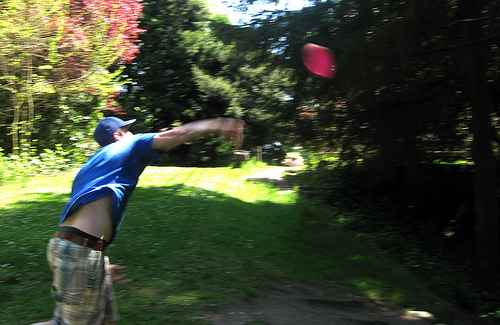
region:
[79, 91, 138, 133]
the cap is blue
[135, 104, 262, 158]
the arm is extended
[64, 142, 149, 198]
the shirt is blue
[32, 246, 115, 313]
the shorts are plaid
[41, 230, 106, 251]
the belt is brown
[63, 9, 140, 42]
the leaves are red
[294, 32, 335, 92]
the object is red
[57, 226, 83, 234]
his underwear is black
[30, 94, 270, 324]
the man is throwing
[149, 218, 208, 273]
the flowers are white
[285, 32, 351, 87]
football in the air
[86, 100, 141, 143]
plain blue ball cap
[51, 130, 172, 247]
plain blue tee shirt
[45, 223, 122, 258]
plain brown leather belt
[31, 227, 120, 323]
pair of plaid shorts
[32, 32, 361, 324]
man tossing leather football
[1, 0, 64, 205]
trees in open field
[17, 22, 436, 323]
man throwing ball downhill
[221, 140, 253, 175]
small wooden postal box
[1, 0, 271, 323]
man standing in forest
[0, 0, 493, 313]
a man in a park throwing a frisbee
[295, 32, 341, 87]
a red frisbee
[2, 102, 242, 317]
a man wearing a blue cap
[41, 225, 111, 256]
a man's belt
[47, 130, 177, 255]
a man's blue shirt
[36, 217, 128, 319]
a man's pair of pants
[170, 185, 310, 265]
this is green grass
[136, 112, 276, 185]
a man's arm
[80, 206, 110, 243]
a man's side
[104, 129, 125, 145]
a man's ear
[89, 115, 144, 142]
Royal blue baseball cap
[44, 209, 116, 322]
Men's plaid pants with brown and white blocks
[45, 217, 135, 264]
Dark brown leather belt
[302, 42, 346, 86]
Light red water balloon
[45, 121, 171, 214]
Bright blue t-shirt with sun reflecting off the shoulder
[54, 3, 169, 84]
Tree with bright pink flowers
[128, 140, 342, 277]
green and yellow grass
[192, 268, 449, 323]
Large patch of brown dirt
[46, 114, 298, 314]
Man throwing ball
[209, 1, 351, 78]
bright blue patch of sky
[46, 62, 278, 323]
man throwing a ball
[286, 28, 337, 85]
ball in motion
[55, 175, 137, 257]
fabric of shirt is lifted up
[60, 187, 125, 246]
skin on back and side is exposed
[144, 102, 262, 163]
arm blurry with motion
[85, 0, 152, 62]
some of the leaves are red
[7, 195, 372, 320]
shadow on the ground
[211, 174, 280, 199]
sunlight shining on the ground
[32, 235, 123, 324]
plaid pants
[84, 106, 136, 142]
blue hat on the head